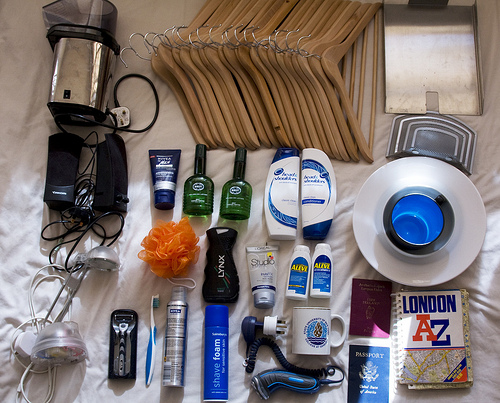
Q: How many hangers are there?
A: Nineteen.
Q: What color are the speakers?
A: Black.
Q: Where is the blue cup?
A: On the plate.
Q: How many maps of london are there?
A: One.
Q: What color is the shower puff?
A: Orange.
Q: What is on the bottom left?
A: A lamp.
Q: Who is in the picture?
A: No one.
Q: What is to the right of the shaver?
A: Toothbrush.